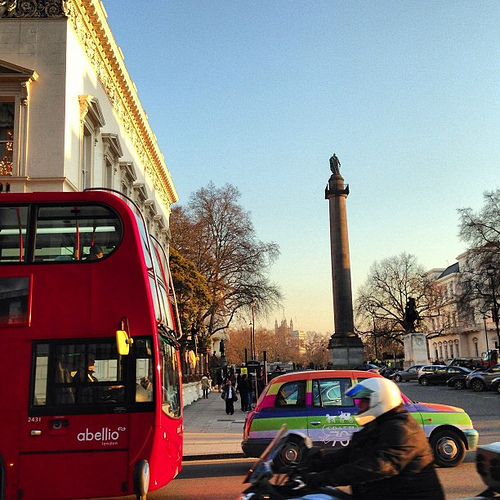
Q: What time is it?
A: Afternoon.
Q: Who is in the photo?
A: Some people.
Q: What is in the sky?
A: Nothing.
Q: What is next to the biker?
A: A bus.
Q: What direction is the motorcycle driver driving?
A: Left.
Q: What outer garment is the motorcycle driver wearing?
A: Black coat.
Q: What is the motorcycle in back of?
A: Red bus.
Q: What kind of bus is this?
A: Double decker bus.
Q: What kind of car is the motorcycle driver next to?
A: Multi-colored 2 door car.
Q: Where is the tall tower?
A: In the street.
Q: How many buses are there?
A: One.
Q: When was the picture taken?
A: Daytime.